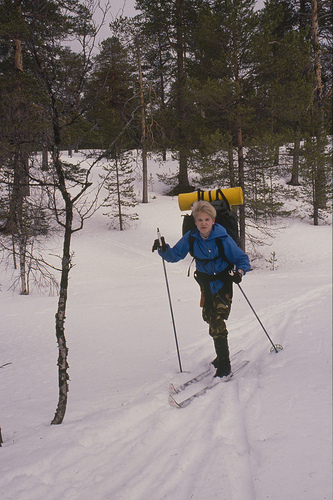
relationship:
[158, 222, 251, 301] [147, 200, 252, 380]
blue sweater on woman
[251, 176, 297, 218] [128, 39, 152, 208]
tree branches of tree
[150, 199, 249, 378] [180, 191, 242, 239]
person wearing backpack